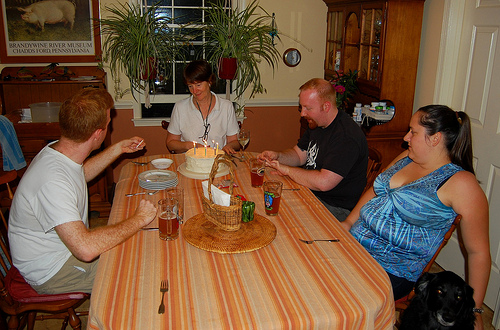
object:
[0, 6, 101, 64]
picture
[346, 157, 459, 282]
blue top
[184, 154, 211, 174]
icing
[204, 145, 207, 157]
candles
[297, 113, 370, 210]
shirt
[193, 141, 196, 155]
candles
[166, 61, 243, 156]
woman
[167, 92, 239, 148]
shirt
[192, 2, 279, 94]
plant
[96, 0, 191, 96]
plant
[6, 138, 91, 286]
t-shirt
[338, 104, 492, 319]
lady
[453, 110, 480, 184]
ponytail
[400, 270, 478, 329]
black dog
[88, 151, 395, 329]
table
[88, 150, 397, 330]
tablecloth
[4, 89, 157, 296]
guy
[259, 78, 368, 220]
guy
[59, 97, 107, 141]
short hair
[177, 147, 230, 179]
birthday cake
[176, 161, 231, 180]
white plate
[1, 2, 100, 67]
frame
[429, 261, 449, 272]
floor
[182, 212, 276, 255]
placemat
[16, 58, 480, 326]
party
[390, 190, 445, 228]
top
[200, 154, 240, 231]
basket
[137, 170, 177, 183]
plate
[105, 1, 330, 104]
wall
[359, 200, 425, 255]
muffintop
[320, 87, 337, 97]
hair